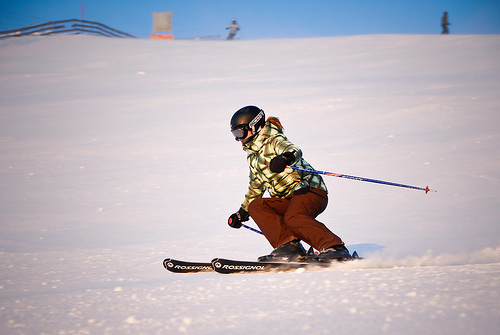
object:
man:
[227, 105, 347, 262]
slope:
[0, 33, 497, 333]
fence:
[0, 18, 138, 38]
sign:
[150, 9, 174, 33]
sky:
[0, 0, 497, 40]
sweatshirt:
[243, 116, 327, 209]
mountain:
[0, 33, 499, 335]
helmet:
[230, 105, 266, 140]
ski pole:
[288, 163, 436, 192]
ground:
[0, 32, 499, 335]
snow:
[4, 34, 149, 156]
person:
[436, 9, 451, 34]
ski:
[161, 258, 222, 274]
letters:
[223, 265, 266, 271]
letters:
[172, 263, 211, 270]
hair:
[265, 113, 285, 135]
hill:
[2, 34, 498, 333]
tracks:
[343, 249, 499, 270]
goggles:
[231, 111, 265, 142]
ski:
[211, 258, 313, 275]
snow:
[217, 271, 493, 299]